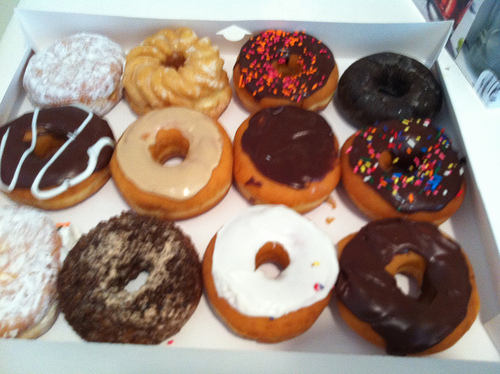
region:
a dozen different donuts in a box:
[0, 26, 475, 355]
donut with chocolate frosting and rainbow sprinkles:
[337, 116, 464, 222]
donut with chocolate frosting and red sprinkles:
[234, 26, 340, 111]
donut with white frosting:
[200, 201, 335, 340]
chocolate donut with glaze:
[62, 211, 195, 341]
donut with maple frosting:
[111, 107, 227, 216]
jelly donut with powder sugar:
[22, 33, 126, 111]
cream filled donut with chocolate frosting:
[230, 105, 341, 203]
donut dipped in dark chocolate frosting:
[338, 51, 440, 124]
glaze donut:
[118, 30, 226, 118]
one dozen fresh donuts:
[0, 18, 498, 366]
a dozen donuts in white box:
[9, 1, 493, 367]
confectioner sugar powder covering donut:
[10, 15, 141, 122]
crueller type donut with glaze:
[119, 19, 237, 116]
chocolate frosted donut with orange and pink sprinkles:
[222, 27, 350, 107]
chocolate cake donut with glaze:
[342, 55, 459, 130]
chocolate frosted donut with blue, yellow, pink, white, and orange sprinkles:
[327, 112, 481, 227]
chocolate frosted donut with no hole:
[227, 110, 346, 201]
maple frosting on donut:
[102, 113, 247, 234]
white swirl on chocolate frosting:
[2, 108, 114, 185]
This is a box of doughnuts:
[2, 2, 496, 372]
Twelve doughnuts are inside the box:
[0, 25, 477, 353]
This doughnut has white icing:
[203, 200, 340, 343]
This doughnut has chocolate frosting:
[334, 215, 481, 356]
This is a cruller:
[125, 27, 231, 115]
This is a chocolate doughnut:
[337, 48, 445, 125]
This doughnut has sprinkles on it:
[341, 118, 466, 223]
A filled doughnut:
[22, 30, 124, 111]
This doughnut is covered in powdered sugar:
[1, 203, 63, 336]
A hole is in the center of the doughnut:
[146, 125, 193, 171]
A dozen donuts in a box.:
[0, 4, 498, 371]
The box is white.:
[0, 3, 497, 371]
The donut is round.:
[19, 26, 129, 114]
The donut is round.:
[226, 25, 342, 117]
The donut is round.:
[330, 45, 449, 135]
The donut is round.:
[103, 94, 235, 227]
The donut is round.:
[226, 102, 346, 208]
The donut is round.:
[338, 111, 474, 233]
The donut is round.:
[327, 210, 484, 359]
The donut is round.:
[201, 198, 346, 350]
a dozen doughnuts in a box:
[0, 5, 494, 349]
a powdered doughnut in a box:
[22, 32, 120, 109]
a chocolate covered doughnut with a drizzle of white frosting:
[2, 111, 113, 196]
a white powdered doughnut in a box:
[3, 204, 67, 352]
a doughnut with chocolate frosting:
[338, 215, 475, 355]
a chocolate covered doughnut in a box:
[57, 212, 199, 338]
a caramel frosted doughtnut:
[110, 102, 231, 212]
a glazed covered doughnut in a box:
[118, 23, 223, 109]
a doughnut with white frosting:
[205, 202, 331, 353]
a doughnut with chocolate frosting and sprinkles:
[341, 118, 462, 224]